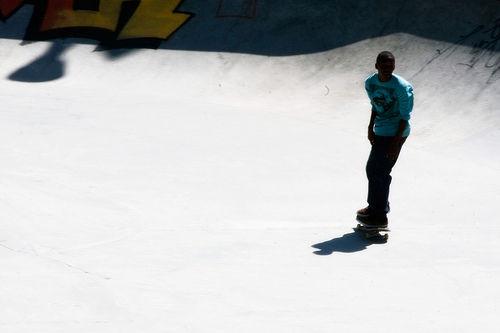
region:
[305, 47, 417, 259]
A young man skateboarding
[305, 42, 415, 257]
A young man skateboarding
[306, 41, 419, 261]
A young man skateboarding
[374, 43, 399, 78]
head of a person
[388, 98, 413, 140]
arm of a person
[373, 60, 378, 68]
ear of a person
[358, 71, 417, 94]
shoulder of a person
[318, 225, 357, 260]
shadow of a person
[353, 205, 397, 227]
feet of a person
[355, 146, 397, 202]
leg of a person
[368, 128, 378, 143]
hand of a person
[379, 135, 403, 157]
hand of a person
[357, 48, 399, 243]
A young boy skate boarding.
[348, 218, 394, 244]
The boy's skateboard.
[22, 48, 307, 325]
The skate park.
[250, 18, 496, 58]
The skate ramps.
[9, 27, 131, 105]
Shadows on the skate ramp.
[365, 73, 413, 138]
The boy wears a blue shirt.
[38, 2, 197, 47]
Graffiti on the skate ramp.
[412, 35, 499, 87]
Marks on the ramp.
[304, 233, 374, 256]
The boy's shadow.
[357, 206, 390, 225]
The boy's skate shoes.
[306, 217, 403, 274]
shadow of the boy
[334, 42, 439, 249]
boy on a skateboard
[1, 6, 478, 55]
shadow of the wall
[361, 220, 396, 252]
front of the skateboard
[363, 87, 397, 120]
decal on the boy's shirt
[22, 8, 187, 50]
graffiti on the wall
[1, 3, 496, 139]
slope of the bowel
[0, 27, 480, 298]
boy in skateboard bowel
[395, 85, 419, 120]
wrinkles in the shirt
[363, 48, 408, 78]
head of the boy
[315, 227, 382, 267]
shadow of skateboarder on the ramp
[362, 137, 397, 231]
dark pants worn by skateboarder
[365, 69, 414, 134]
blue shirt worn by the skateboarder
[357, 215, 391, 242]
skateboard being ridden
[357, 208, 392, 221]
shoes worn by the skateboarder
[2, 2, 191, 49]
yellow and black graffiti on the ramp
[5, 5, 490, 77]
shadows on the back of the ramp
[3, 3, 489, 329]
ramp skateboarder is using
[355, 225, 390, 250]
wheels on the skateboard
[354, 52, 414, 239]
skateboarder riding on the ramp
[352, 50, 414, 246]
human rides skateboard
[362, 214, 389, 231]
sneaker worn by human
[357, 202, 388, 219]
sneaker worn by human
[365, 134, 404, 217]
pants worn by human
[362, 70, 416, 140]
shirt worn by human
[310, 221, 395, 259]
shadow cast by human